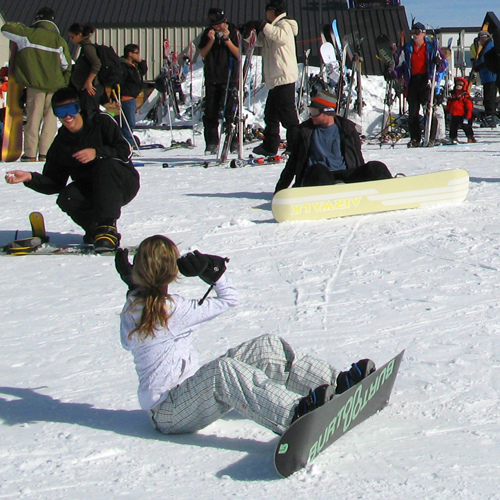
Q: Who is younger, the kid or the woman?
A: The kid is younger than the woman.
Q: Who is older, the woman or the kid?
A: The woman is older than the kid.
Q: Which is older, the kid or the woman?
A: The woman is older than the kid.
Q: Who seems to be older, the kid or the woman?
A: The woman is older than the kid.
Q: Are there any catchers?
A: No, there are no catchers.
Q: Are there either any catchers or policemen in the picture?
A: No, there are no catchers or policemen.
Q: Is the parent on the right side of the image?
A: Yes, the parent is on the right of the image.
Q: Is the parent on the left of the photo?
A: No, the parent is on the right of the image.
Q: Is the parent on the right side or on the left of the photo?
A: The parent is on the right of the image.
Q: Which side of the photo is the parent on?
A: The parent is on the right of the image.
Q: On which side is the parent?
A: The parent is on the right of the image.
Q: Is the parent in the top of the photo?
A: Yes, the parent is in the top of the image.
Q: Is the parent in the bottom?
A: No, the parent is in the top of the image.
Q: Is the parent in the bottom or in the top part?
A: The parent is in the top of the image.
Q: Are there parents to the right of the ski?
A: Yes, there is a parent to the right of the ski.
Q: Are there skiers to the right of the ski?
A: No, there is a parent to the right of the ski.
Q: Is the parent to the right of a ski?
A: Yes, the parent is to the right of a ski.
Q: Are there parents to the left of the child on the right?
A: Yes, there is a parent to the left of the child.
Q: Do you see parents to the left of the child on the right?
A: Yes, there is a parent to the left of the child.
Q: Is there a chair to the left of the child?
A: No, there is a parent to the left of the child.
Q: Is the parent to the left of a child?
A: Yes, the parent is to the left of a child.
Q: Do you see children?
A: Yes, there is a child.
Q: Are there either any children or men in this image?
A: Yes, there is a child.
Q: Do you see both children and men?
A: Yes, there are both a child and a man.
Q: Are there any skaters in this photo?
A: No, there are no skaters.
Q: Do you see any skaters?
A: No, there are no skaters.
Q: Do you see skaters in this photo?
A: No, there are no skaters.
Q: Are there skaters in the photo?
A: No, there are no skaters.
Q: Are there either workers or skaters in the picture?
A: No, there are no skaters or workers.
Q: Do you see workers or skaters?
A: No, there are no skaters or workers.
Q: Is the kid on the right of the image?
A: Yes, the kid is on the right of the image.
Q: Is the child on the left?
A: No, the child is on the right of the image.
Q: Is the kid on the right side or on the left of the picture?
A: The kid is on the right of the image.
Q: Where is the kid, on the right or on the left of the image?
A: The kid is on the right of the image.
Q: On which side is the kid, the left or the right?
A: The kid is on the right of the image.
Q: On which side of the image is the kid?
A: The kid is on the right of the image.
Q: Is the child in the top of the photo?
A: Yes, the child is in the top of the image.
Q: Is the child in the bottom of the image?
A: No, the child is in the top of the image.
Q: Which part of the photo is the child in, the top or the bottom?
A: The child is in the top of the image.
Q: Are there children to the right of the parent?
A: Yes, there is a child to the right of the parent.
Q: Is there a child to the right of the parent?
A: Yes, there is a child to the right of the parent.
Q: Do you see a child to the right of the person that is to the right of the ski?
A: Yes, there is a child to the right of the parent.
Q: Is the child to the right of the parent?
A: Yes, the child is to the right of the parent.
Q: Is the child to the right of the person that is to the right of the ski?
A: Yes, the child is to the right of the parent.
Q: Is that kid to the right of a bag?
A: No, the kid is to the right of the parent.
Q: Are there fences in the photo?
A: No, there are no fences.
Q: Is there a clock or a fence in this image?
A: No, there are no fences or clocks.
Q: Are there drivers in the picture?
A: No, there are no drivers.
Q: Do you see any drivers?
A: No, there are no drivers.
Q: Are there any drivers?
A: No, there are no drivers.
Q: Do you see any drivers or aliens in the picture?
A: No, there are no drivers or aliens.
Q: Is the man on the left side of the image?
A: Yes, the man is on the left of the image.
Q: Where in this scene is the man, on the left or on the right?
A: The man is on the left of the image.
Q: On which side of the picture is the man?
A: The man is on the left of the image.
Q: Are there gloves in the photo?
A: Yes, there are gloves.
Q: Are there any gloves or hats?
A: Yes, there are gloves.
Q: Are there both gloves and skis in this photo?
A: Yes, there are both gloves and skis.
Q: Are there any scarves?
A: No, there are no scarves.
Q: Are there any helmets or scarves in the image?
A: No, there are no scarves or helmets.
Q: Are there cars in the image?
A: No, there are no cars.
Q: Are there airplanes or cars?
A: No, there are no cars or airplanes.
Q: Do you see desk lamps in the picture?
A: No, there are no desk lamps.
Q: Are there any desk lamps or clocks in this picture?
A: No, there are no desk lamps or clocks.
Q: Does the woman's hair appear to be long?
A: Yes, the hair is long.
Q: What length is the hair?
A: The hair is long.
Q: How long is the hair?
A: The hair is long.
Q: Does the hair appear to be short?
A: No, the hair is long.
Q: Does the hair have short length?
A: No, the hair is long.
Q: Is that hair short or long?
A: The hair is long.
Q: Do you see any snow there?
A: Yes, there is snow.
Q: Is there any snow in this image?
A: Yes, there is snow.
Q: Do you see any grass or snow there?
A: Yes, there is snow.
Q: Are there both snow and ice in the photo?
A: No, there is snow but no ice.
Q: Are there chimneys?
A: No, there are no chimneys.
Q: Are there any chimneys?
A: No, there are no chimneys.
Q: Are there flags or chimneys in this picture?
A: No, there are no chimneys or flags.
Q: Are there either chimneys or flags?
A: No, there are no chimneys or flags.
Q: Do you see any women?
A: Yes, there is a woman.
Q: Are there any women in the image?
A: Yes, there is a woman.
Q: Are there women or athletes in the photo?
A: Yes, there is a woman.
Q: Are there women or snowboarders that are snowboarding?
A: Yes, the woman is snowboarding.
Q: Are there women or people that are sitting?
A: Yes, the woman is sitting.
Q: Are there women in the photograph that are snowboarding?
A: Yes, there is a woman that is snowboarding.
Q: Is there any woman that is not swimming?
A: Yes, there is a woman that is snowboarding.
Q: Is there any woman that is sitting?
A: Yes, there is a woman that is sitting.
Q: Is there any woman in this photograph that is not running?
A: Yes, there is a woman that is sitting.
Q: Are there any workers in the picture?
A: No, there are no workers.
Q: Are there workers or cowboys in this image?
A: No, there are no workers or cowboys.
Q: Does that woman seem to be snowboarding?
A: Yes, the woman is snowboarding.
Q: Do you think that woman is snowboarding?
A: Yes, the woman is snowboarding.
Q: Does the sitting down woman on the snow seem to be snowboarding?
A: Yes, the woman is snowboarding.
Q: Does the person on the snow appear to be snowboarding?
A: Yes, the woman is snowboarding.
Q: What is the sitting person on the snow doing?
A: The woman is snowboarding.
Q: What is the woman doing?
A: The woman is snowboarding.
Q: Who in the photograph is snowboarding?
A: The woman is snowboarding.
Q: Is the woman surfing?
A: No, the woman is snowboarding.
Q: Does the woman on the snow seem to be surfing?
A: No, the woman is snowboarding.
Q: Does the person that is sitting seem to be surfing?
A: No, the woman is snowboarding.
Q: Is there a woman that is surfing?
A: No, there is a woman but she is snowboarding.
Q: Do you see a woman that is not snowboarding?
A: No, there is a woman but she is snowboarding.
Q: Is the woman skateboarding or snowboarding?
A: The woman is snowboarding.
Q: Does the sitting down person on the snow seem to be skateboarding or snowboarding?
A: The woman is snowboarding.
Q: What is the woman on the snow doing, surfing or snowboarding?
A: The woman is snowboarding.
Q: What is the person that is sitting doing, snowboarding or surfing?
A: The woman is snowboarding.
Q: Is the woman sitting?
A: Yes, the woman is sitting.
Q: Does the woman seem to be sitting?
A: Yes, the woman is sitting.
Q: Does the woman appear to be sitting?
A: Yes, the woman is sitting.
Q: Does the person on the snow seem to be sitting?
A: Yes, the woman is sitting.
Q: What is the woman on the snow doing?
A: The woman is sitting.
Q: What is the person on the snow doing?
A: The woman is sitting.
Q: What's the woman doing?
A: The woman is sitting.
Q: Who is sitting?
A: The woman is sitting.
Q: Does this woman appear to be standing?
A: No, the woman is sitting.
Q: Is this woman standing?
A: No, the woman is sitting.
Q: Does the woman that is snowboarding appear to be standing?
A: No, the woman is sitting.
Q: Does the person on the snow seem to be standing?
A: No, the woman is sitting.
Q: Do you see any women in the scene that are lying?
A: No, there is a woman but she is sitting.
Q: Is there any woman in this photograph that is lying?
A: No, there is a woman but she is sitting.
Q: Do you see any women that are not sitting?
A: No, there is a woman but she is sitting.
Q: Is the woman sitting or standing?
A: The woman is sitting.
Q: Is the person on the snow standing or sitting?
A: The woman is sitting.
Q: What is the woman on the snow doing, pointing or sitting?
A: The woman is sitting.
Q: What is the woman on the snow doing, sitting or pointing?
A: The woman is sitting.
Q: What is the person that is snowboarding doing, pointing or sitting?
A: The woman is sitting.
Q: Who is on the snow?
A: The woman is on the snow.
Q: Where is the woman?
A: The woman is on the snow.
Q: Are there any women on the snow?
A: Yes, there is a woman on the snow.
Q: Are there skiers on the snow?
A: No, there is a woman on the snow.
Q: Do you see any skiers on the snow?
A: No, there is a woman on the snow.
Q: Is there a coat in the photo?
A: Yes, there is a coat.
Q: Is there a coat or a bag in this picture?
A: Yes, there is a coat.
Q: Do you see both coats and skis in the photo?
A: Yes, there are both a coat and skis.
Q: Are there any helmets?
A: No, there are no helmets.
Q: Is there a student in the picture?
A: No, there are no students.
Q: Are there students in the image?
A: No, there are no students.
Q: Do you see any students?
A: No, there are no students.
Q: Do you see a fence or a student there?
A: No, there are no students or fences.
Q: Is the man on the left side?
A: Yes, the man is on the left of the image.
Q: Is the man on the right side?
A: No, the man is on the left of the image.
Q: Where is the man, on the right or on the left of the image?
A: The man is on the left of the image.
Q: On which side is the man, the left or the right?
A: The man is on the left of the image.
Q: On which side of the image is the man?
A: The man is on the left of the image.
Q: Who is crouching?
A: The man is crouching.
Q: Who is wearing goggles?
A: The man is wearing goggles.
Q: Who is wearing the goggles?
A: The man is wearing goggles.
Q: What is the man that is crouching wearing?
A: The man is wearing goggles.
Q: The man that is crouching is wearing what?
A: The man is wearing goggles.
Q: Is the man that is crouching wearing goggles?
A: Yes, the man is wearing goggles.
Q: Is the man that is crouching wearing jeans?
A: No, the man is wearing goggles.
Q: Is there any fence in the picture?
A: No, there are no fences.